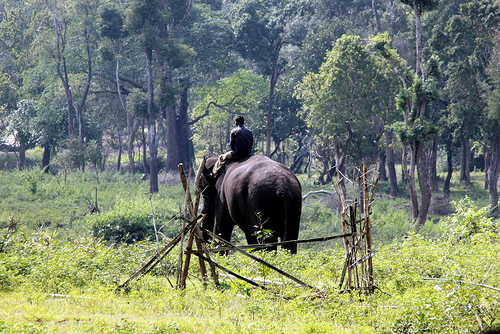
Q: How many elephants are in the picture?
A: One.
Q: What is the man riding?
A: Elephant.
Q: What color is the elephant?
A: Gray.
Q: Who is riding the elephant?
A: A man.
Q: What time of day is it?
A: Daytime.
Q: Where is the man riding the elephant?
A: Back.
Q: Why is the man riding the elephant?
A: Transportation.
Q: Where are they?
A: Jungle.